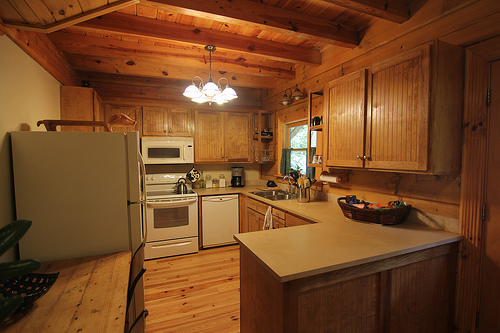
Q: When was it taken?
A: Daytime.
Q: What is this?
A: A kitchen.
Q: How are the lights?
A: On.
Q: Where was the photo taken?
A: In a kitchen.